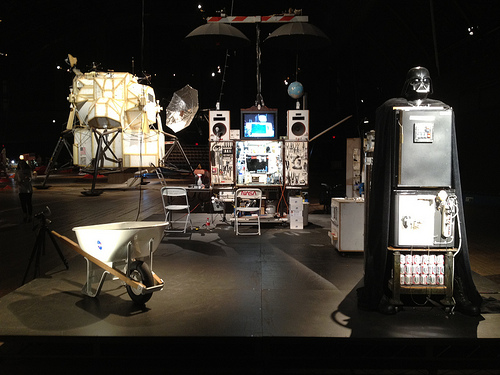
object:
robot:
[370, 63, 473, 321]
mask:
[411, 76, 431, 94]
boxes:
[396, 106, 452, 189]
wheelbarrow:
[50, 218, 171, 305]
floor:
[6, 181, 499, 334]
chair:
[231, 189, 264, 236]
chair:
[161, 185, 192, 233]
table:
[160, 183, 284, 219]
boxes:
[206, 109, 232, 141]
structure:
[73, 69, 161, 169]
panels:
[142, 131, 159, 155]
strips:
[143, 139, 148, 154]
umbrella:
[164, 83, 200, 132]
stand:
[175, 140, 199, 182]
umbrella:
[181, 22, 244, 43]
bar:
[203, 13, 309, 24]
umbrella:
[265, 24, 330, 43]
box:
[235, 141, 285, 185]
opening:
[246, 156, 269, 172]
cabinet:
[328, 198, 364, 253]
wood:
[335, 201, 345, 253]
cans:
[399, 254, 406, 264]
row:
[401, 274, 445, 284]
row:
[400, 254, 447, 265]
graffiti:
[240, 190, 258, 197]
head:
[403, 65, 436, 97]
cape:
[355, 96, 499, 315]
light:
[166, 106, 187, 127]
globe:
[288, 82, 304, 109]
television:
[239, 108, 280, 141]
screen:
[243, 115, 275, 138]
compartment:
[397, 254, 411, 275]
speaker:
[208, 110, 232, 141]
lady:
[14, 159, 35, 224]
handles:
[48, 229, 165, 293]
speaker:
[286, 109, 310, 140]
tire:
[123, 261, 156, 305]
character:
[403, 66, 433, 100]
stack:
[400, 253, 445, 287]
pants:
[17, 189, 34, 218]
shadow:
[15, 278, 146, 330]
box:
[394, 108, 453, 188]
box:
[392, 186, 458, 244]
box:
[389, 247, 454, 296]